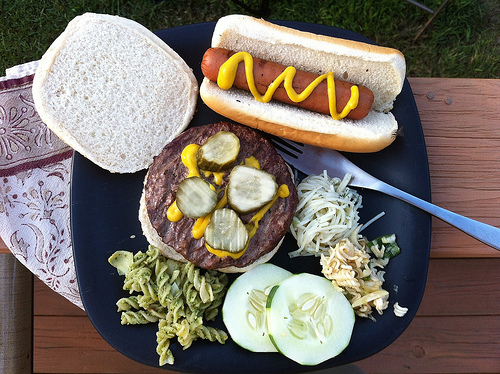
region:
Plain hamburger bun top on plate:
[32, 13, 196, 173]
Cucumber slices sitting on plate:
[221, 260, 353, 368]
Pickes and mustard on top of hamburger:
[167, 129, 289, 259]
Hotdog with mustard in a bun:
[201, 14, 407, 154]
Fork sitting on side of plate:
[271, 133, 499, 250]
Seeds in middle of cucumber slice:
[286, 290, 328, 341]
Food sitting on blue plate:
[67, 14, 433, 372]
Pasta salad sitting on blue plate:
[106, 248, 234, 365]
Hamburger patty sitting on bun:
[145, 121, 300, 268]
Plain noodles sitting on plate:
[287, 170, 386, 257]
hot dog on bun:
[211, 38, 395, 152]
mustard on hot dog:
[215, 45, 377, 126]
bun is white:
[192, 35, 386, 143]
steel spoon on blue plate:
[291, 145, 495, 233]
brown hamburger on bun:
[157, 134, 281, 271]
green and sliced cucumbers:
[221, 267, 359, 369]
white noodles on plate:
[301, 157, 346, 231]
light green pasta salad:
[92, 260, 214, 351]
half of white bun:
[47, 35, 171, 145]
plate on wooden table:
[92, 55, 424, 362]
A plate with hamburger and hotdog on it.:
[16, 8, 448, 372]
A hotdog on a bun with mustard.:
[187, 8, 412, 143]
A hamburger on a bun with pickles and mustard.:
[133, 108, 291, 266]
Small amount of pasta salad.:
[99, 238, 221, 368]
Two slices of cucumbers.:
[221, 253, 364, 365]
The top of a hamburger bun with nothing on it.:
[25, 3, 195, 169]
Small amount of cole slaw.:
[298, 169, 363, 264]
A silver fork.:
[257, 110, 495, 245]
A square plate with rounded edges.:
[57, 22, 444, 372]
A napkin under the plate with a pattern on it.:
[0, 58, 93, 321]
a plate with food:
[37, 7, 497, 369]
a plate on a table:
[29, 19, 333, 357]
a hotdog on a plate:
[173, 16, 451, 164]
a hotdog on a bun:
[186, 1, 482, 186]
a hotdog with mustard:
[203, 12, 492, 212]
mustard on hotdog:
[214, 11, 349, 158]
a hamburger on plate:
[47, 16, 326, 277]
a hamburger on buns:
[128, 43, 398, 305]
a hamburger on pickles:
[91, 88, 392, 286]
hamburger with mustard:
[144, 94, 309, 261]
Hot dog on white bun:
[197, 8, 414, 153]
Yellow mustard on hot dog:
[189, 39, 386, 128]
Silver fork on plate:
[303, 132, 483, 252]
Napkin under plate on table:
[13, 171, 55, 258]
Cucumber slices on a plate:
[220, 258, 350, 372]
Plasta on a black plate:
[100, 233, 227, 370]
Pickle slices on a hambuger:
[172, 128, 281, 263]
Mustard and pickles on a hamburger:
[130, 117, 300, 279]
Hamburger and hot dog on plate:
[130, 9, 410, 273]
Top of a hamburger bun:
[25, 5, 202, 197]